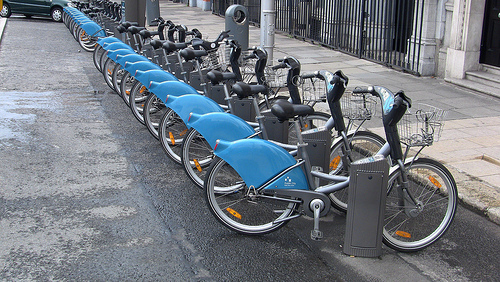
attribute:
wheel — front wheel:
[383, 158, 458, 253]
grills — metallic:
[297, 5, 423, 58]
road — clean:
[7, 10, 496, 280]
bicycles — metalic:
[192, 90, 496, 264]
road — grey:
[29, 112, 137, 253]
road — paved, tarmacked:
[7, 29, 142, 278]